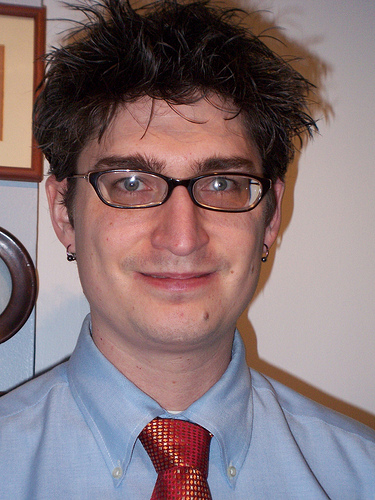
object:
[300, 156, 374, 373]
part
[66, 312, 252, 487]
part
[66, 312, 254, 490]
collar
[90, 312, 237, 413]
part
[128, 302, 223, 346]
chin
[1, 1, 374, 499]
man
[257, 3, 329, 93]
part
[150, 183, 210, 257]
nose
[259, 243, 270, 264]
part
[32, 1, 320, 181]
hair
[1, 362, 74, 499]
shoulder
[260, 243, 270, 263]
earrings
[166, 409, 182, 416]
white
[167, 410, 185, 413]
shirt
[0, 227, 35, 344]
circle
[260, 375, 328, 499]
crease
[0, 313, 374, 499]
shirt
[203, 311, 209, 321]
mole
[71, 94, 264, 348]
face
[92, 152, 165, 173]
brow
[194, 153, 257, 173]
bushy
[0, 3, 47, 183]
brown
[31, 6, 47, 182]
edge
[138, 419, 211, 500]
tie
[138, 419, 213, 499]
red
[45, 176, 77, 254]
ear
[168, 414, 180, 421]
button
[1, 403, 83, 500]
blue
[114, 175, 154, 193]
eye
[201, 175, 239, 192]
eye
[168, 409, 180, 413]
sliver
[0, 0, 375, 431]
wall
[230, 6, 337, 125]
shadow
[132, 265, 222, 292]
smiling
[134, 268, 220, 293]
mouth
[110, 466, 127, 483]
button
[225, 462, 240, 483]
button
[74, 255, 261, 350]
shaved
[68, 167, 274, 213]
glasses